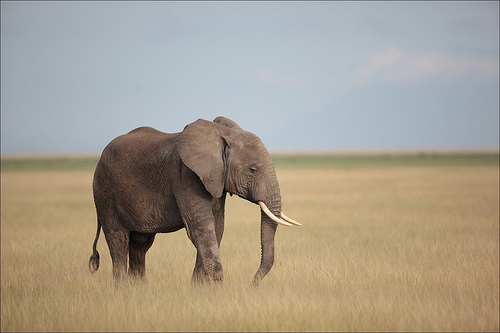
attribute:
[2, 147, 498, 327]
grass — brown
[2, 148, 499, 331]
brown grass — tall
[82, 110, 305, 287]
elephant — large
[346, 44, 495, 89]
clouds — white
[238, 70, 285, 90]
clouds — white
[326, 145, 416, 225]
grass — brown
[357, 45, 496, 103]
cloud — white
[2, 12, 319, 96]
sky — blue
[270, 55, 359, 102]
clouds — white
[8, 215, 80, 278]
grass — brown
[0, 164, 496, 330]
grass — brown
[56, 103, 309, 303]
elephant — brown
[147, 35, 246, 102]
clouds — white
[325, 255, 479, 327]
grass — brown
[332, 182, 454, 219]
grass — brown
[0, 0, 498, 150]
sky — blue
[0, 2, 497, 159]
clouds — white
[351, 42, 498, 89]
cloud — white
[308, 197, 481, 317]
grasses — brown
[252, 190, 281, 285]
trunk — long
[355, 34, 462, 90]
clouds — white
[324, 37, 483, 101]
clouds — white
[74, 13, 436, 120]
sky — blue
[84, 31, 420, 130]
sky — blue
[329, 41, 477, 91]
clouds — white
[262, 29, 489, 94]
clouds — white